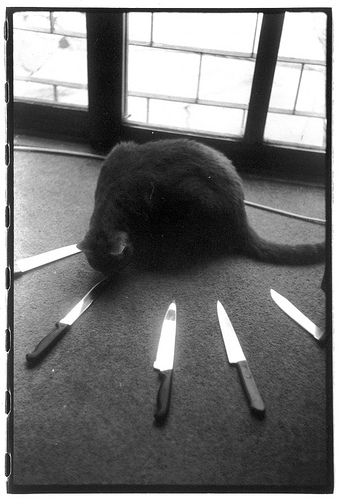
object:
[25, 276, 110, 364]
knife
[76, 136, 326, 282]
cat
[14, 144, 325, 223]
cord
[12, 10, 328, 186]
window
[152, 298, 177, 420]
knife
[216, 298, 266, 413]
knife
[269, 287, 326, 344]
knife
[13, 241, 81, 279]
knife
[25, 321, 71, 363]
handle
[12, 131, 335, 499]
floor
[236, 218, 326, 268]
tail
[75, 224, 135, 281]
head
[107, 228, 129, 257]
ears